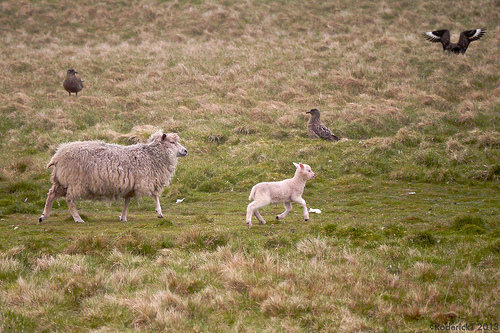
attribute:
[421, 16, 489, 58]
bird — flying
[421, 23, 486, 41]
wings — spread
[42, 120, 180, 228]
sheep — wooly, furry, large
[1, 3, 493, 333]
field — dead grass, grassy, green, dry, brown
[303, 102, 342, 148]
bird — looking around, looking for food, small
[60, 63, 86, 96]
bird — looking around, looking for food, small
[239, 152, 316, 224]
lamb — prancing around, small, furry, white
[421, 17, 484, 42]
marks — white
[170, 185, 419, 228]
trash — white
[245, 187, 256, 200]
tail — white